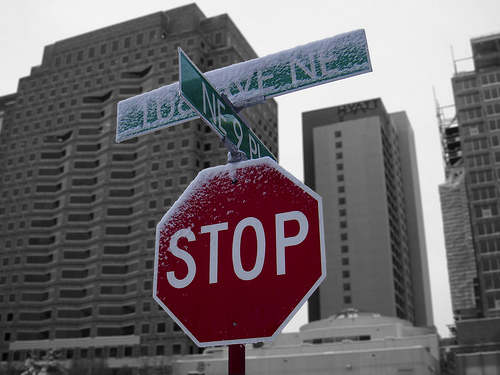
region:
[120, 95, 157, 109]
Snow on the street sign.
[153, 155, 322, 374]
The red and white stop sign.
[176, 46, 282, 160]
The "NE 9 PL" street sign.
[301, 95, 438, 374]
The tall Hyatt building.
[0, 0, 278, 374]
A tall gray building in background.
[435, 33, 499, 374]
A building in repair.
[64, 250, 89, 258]
The window on the building.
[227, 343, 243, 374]
The red pole of the stop sign.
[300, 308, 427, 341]
The top of the lower building.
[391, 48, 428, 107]
The pale blue sky.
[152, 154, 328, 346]
stop sign with snow on it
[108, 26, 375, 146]
Street sign with snow on it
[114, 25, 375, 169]
green street signs with snow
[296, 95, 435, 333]
building with the word Hyatt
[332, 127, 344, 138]
square window on Hyatt building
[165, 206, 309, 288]
the word stop on a sign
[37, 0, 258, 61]
top floor of a tall building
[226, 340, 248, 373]
pole holding a stop sign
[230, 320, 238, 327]
metal screw to mount the stop sign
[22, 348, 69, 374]
a tree with snow on it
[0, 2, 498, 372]
A scene of grey buildings.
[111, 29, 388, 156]
Two green and white street signs.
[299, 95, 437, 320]
The tall grey Hyatt building.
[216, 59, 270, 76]
Snow on the street signs.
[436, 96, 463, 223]
Area of reconstruction on the building.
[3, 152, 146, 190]
The windows on the left building.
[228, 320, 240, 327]
The nail in the stop sign.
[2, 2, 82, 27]
The pale cloudy sky.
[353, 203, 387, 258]
The cement wall of the middle building.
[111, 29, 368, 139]
Snow on a street sign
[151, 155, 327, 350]
A stop sign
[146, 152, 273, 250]
Snow on the stop sign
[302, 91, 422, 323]
A tall gray building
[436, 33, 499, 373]
A tall gray building on the right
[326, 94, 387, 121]
The Word "Hyatt" on top of the building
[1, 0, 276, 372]
A tall, wide gray building with several windows, some curved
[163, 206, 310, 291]
The word Stop in white paint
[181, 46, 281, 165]
Diagonal street sign without snow on it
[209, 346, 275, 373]
The stop sign pole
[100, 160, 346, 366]
the stop sign is red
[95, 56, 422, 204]
the signs are covered with snow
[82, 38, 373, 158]
the street signs are green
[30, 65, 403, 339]
this is an outdoor scene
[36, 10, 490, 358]
this is a street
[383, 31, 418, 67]
the sky is covered by clouds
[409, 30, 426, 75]
the clouds are grey in color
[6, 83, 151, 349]
the buildings have many windows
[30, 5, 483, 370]
buildings are in the background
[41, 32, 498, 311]
the buildings have many floors